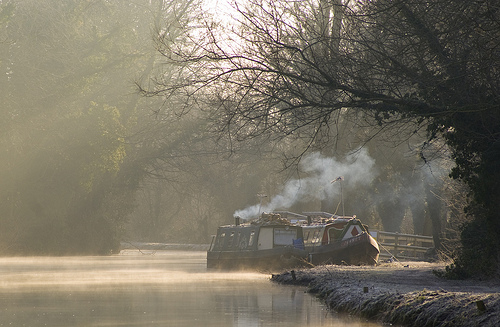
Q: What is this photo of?
A: A boat.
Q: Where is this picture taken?
A: In a river.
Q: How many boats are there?
A: 1.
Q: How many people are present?
A: 0.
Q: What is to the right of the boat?
A: A fence.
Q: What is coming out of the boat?
A: Smoke.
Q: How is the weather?
A: Sunny.